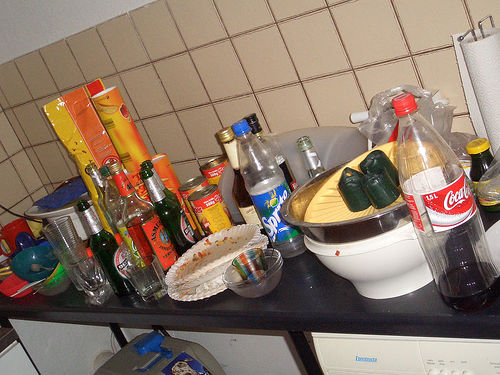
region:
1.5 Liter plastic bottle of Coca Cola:
[382, 95, 497, 318]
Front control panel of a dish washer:
[303, 331, 498, 372]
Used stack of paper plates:
[158, 222, 278, 285]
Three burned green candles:
[321, 145, 404, 205]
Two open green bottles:
[132, 159, 202, 254]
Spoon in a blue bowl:
[28, 258, 58, 278]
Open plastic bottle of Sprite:
[228, 119, 311, 260]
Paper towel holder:
[452, 23, 499, 140]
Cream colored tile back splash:
[147, 27, 351, 114]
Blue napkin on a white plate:
[29, 169, 113, 210]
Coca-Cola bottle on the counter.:
[388, 97, 498, 308]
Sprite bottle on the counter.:
[229, 124, 304, 250]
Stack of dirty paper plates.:
[159, 220, 263, 302]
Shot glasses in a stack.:
[43, 217, 109, 295]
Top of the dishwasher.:
[319, 341, 499, 371]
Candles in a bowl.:
[325, 147, 404, 199]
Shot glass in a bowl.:
[228, 240, 270, 280]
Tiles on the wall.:
[172, 30, 320, 90]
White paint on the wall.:
[8, 0, 69, 42]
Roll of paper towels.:
[446, 28, 498, 161]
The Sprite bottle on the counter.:
[228, 119, 307, 260]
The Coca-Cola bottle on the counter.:
[386, 97, 496, 305]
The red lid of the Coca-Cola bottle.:
[385, 95, 417, 113]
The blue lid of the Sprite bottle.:
[229, 117, 253, 136]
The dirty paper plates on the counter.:
[158, 225, 274, 302]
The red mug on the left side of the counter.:
[2, 220, 39, 260]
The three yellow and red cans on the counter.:
[172, 157, 234, 231]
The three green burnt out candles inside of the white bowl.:
[323, 145, 398, 212]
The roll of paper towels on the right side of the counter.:
[459, 17, 499, 139]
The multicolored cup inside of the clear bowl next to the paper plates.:
[229, 253, 279, 276]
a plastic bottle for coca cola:
[386, 87, 499, 316]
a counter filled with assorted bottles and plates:
[5, 190, 499, 362]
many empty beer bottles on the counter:
[83, 170, 198, 286]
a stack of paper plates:
[165, 222, 263, 306]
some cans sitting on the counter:
[179, 154, 226, 241]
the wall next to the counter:
[1, 10, 496, 182]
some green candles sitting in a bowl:
[329, 145, 392, 208]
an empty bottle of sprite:
[231, 122, 296, 256]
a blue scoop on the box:
[135, 333, 177, 361]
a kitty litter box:
[84, 338, 220, 373]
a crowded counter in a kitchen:
[11, 7, 498, 367]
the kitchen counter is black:
[7, 187, 499, 339]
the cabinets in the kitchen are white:
[3, 302, 304, 373]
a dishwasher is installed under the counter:
[304, 322, 499, 374]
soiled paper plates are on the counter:
[163, 222, 275, 306]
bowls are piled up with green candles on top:
[286, 142, 451, 304]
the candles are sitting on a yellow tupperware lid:
[301, 138, 437, 223]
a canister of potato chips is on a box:
[91, 85, 177, 200]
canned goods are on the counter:
[177, 170, 232, 243]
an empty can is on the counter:
[199, 150, 234, 187]